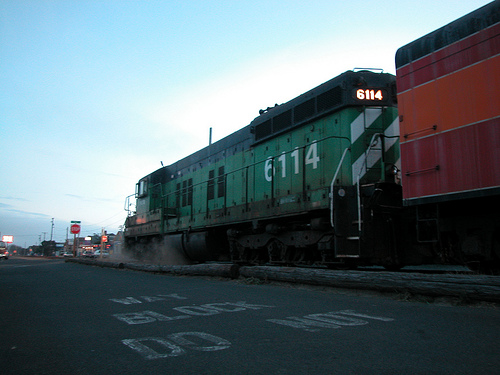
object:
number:
[357, 89, 365, 100]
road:
[0, 256, 500, 374]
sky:
[0, 0, 500, 249]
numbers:
[365, 89, 370, 100]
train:
[124, 0, 500, 273]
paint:
[111, 312, 157, 326]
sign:
[70, 220, 81, 234]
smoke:
[94, 230, 191, 270]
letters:
[120, 335, 187, 359]